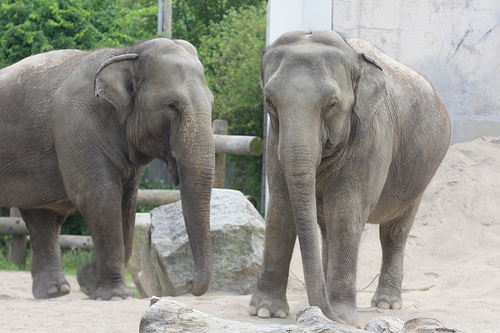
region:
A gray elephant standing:
[248, 28, 452, 320]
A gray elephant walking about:
[0, 36, 217, 301]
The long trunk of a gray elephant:
[173, 128, 213, 295]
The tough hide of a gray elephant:
[3, 75, 56, 198]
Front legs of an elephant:
[71, 175, 138, 300]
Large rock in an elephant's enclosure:
[136, 188, 296, 292]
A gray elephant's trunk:
[282, 148, 339, 324]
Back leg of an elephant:
[16, 203, 71, 298]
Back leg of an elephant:
[368, 205, 403, 307]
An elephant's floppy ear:
[92, 51, 138, 120]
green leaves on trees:
[1, 2, 261, 204]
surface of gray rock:
[146, 193, 265, 296]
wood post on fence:
[0, 117, 265, 267]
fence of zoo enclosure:
[0, 117, 262, 264]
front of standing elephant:
[249, 28, 450, 317]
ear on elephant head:
[93, 53, 140, 125]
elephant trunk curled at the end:
[183, 162, 215, 295]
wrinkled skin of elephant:
[72, 107, 128, 197]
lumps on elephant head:
[267, 29, 351, 86]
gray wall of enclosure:
[264, 4, 496, 146]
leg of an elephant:
[368, 225, 434, 317]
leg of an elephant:
[319, 196, 374, 302]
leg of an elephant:
[253, 227, 303, 293]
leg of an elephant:
[96, 218, 147, 282]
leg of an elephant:
[123, 192, 156, 259]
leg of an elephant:
[39, 221, 81, 273]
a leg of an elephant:
[380, 230, 424, 289]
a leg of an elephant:
[297, 220, 369, 302]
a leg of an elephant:
[243, 227, 293, 294]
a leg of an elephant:
[91, 204, 144, 268]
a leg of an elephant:
[366, 215, 418, 298]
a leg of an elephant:
[314, 197, 371, 285]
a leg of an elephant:
[248, 236, 308, 318]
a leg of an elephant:
[28, 224, 87, 292]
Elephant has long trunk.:
[177, 138, 218, 274]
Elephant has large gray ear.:
[92, 60, 134, 111]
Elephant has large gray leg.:
[90, 210, 140, 316]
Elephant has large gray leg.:
[27, 227, 76, 311]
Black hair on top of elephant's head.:
[138, 28, 180, 61]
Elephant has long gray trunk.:
[304, 225, 331, 298]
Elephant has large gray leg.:
[251, 161, 290, 302]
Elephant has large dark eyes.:
[261, 87, 353, 120]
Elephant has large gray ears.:
[342, 46, 387, 106]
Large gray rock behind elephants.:
[158, 198, 290, 273]